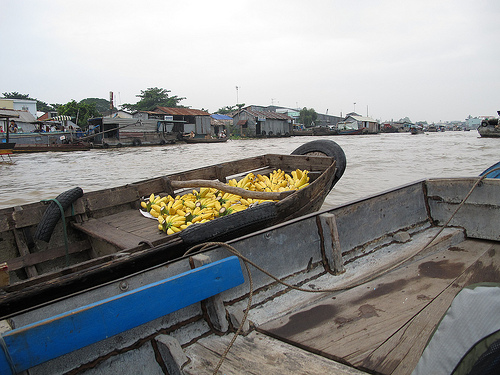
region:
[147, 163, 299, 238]
many bunches of bananas in a boat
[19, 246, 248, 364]
blue wood plank on the side of the boat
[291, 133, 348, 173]
black tire on the front of the boat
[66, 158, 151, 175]
calm black water of the river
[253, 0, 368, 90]
cloudy white skies over the river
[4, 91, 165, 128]
trees growing next to the river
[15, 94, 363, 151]
many house boats on the river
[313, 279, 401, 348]
grey wood deck of the boat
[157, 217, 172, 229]
green tops of the bananas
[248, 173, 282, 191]
smooth yellow skin of the bananas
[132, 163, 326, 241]
Yellow bananas in the boat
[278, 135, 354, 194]
Tire at the end of the boat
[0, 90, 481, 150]
Houses on the side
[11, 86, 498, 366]
Boats are in motion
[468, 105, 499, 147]
Another boat in the distance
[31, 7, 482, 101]
The sky is cloudy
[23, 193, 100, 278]
Wires in the boat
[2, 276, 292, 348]
A blue bar here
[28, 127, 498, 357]
Boat is made of wood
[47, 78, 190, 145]
Trees behind the houses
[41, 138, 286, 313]
the wooden boat is brown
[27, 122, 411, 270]
the wooden boat is brown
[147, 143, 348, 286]
the bananas are yellow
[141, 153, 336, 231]
bananas on the boat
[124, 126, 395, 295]
bananas on the boat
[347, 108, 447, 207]
the water is murky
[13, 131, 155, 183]
the water is murky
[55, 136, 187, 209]
the water is murky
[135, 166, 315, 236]
Banana's in a boat.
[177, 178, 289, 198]
Wooden pole across boat.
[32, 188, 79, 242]
Piece of tire attached to boat.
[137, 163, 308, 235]
Yellow banana in bunches.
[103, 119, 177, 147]
Rv parked along side river.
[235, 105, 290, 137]
Metal topped home along river.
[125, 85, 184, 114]
Tall green rises above homes.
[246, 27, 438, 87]
White hazy cloudless day.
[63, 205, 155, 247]
Wooden shelf inside boat.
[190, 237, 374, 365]
Thick rope strung across boat.